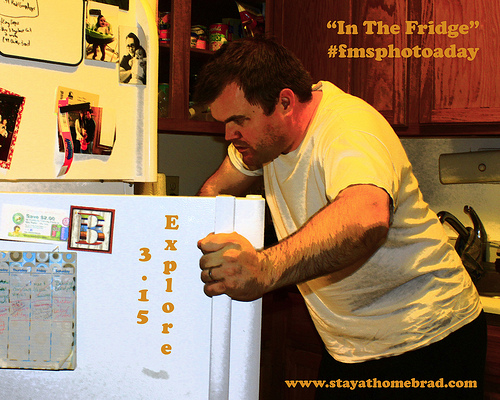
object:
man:
[195, 35, 490, 396]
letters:
[157, 208, 186, 359]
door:
[0, 188, 271, 397]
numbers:
[132, 242, 156, 329]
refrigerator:
[0, 1, 162, 181]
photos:
[116, 22, 150, 88]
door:
[3, 0, 163, 188]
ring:
[203, 266, 216, 280]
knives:
[460, 202, 490, 262]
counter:
[438, 275, 499, 324]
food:
[210, 21, 228, 54]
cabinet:
[179, 0, 271, 133]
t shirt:
[223, 80, 483, 367]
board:
[0, 2, 88, 69]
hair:
[193, 36, 314, 113]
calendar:
[0, 248, 82, 371]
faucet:
[433, 210, 471, 242]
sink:
[473, 266, 500, 288]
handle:
[194, 197, 244, 400]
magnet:
[63, 203, 116, 253]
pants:
[313, 314, 488, 398]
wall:
[163, 133, 498, 250]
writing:
[0, 1, 41, 49]